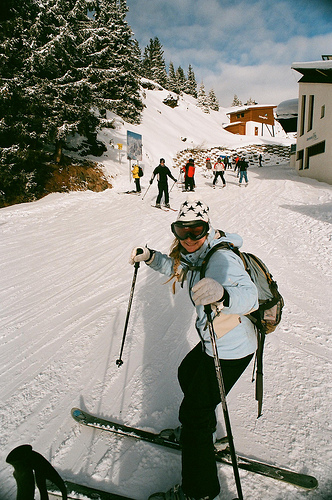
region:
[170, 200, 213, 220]
the cap is whhite with black stars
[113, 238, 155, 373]
the lady is holding a black rod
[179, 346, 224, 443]
the pants are blackish in colour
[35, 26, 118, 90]
the tree is covered with snow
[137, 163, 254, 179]
the people are skiing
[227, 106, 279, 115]
the roof is covered with snow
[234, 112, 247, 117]
the brown wall has two windows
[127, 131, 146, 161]
the billboard is blue and white in colour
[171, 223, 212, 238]
the lady has some googles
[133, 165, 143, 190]
the person is carring a black backpack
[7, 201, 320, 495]
a woman on skies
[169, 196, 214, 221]
she is wearing a hat with stars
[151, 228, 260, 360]
she is wearing a blue coat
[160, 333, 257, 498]
she is wearing black pants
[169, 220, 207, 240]
she is wearing thick goggles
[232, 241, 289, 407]
she is wearing a backpack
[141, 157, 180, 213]
a skier behind the girl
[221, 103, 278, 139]
a ski lodge on the hill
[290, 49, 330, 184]
a building behind the woman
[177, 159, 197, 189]
a skier in a red jacket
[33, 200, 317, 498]
Woman is skiing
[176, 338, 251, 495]
Pants are black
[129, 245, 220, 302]
The gloves are white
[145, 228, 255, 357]
The jacket is blue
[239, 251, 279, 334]
Woman has a backpack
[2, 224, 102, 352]
Tracks in the snow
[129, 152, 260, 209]
People in the background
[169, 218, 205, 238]
Woman is wearing goggles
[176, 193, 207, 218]
Cap is white with black stars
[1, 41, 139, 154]
Snow on the tree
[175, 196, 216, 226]
A black/white star hat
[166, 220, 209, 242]
A pair of black ski goggles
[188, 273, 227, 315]
A think grey glove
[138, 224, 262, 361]
A light blue sweater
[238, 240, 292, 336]
A grey/orange backpack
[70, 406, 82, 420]
A blue logo sign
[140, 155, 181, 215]
A man skiing in the backround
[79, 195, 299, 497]
A woman smiling and skiing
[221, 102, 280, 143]
A brown house/shack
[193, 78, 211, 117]
A snow covered pine tree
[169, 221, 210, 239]
Winter sunglasses on a woman.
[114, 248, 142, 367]
A skiiing stick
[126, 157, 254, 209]
A group of people ready to skii.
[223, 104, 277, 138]
A building in the snow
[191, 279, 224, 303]
A gray glove worn on the hand of a woman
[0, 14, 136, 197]
Pine trees growing in the mountans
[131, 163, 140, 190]
person wearing a yellow jacket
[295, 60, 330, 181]
A building on the side of a mountain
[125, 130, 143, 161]
A sign in the winter filled landscape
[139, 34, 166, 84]
A pine tree growing in the winter